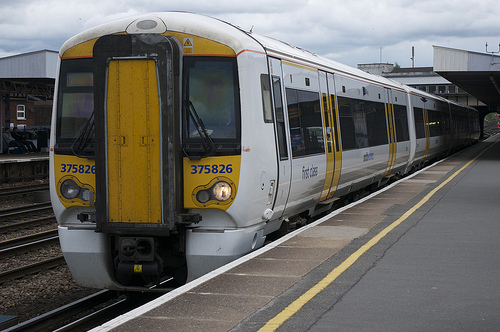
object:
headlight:
[195, 180, 232, 203]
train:
[384, 88, 396, 176]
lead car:
[48, 12, 301, 292]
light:
[212, 181, 232, 201]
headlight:
[59, 178, 93, 201]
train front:
[48, 11, 249, 291]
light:
[59, 179, 80, 200]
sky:
[0, 0, 499, 71]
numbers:
[190, 162, 241, 175]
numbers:
[60, 155, 97, 179]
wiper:
[182, 101, 215, 161]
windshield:
[182, 57, 235, 144]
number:
[190, 164, 233, 174]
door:
[106, 58, 162, 224]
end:
[50, 29, 261, 293]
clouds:
[231, 0, 500, 64]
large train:
[49, 11, 484, 294]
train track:
[2, 284, 176, 331]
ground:
[317, 52, 380, 97]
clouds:
[1, 0, 499, 67]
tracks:
[0, 164, 135, 332]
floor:
[124, 131, 192, 186]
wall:
[232, 146, 292, 209]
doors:
[318, 71, 344, 203]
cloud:
[361, 0, 500, 37]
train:
[48, 11, 294, 293]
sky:
[257, 1, 484, 49]